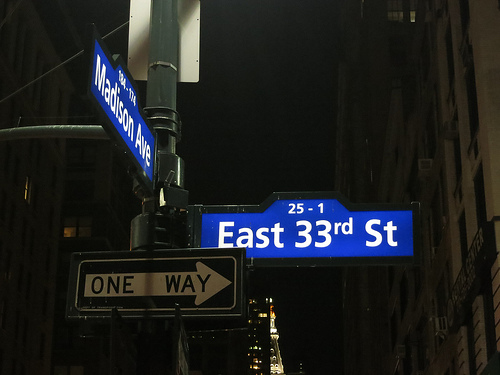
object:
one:
[86, 273, 136, 296]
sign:
[72, 250, 243, 317]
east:
[217, 222, 286, 250]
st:
[363, 215, 397, 243]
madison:
[89, 51, 132, 142]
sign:
[86, 23, 156, 190]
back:
[131, 1, 198, 81]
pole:
[129, 0, 185, 368]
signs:
[82, 0, 417, 322]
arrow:
[82, 264, 232, 303]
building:
[335, 1, 495, 371]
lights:
[386, 1, 418, 25]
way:
[164, 274, 210, 294]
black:
[147, 261, 182, 271]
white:
[97, 69, 106, 77]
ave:
[136, 121, 152, 169]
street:
[284, 199, 330, 218]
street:
[116, 65, 142, 109]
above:
[116, 1, 204, 80]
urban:
[2, 1, 498, 372]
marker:
[118, 0, 204, 89]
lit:
[63, 210, 93, 240]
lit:
[185, 204, 421, 265]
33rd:
[295, 217, 359, 252]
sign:
[435, 223, 492, 344]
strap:
[146, 61, 180, 72]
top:
[328, 2, 497, 74]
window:
[441, 107, 462, 181]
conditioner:
[443, 119, 457, 140]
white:
[144, 279, 162, 292]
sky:
[169, 9, 392, 197]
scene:
[22, 10, 484, 357]